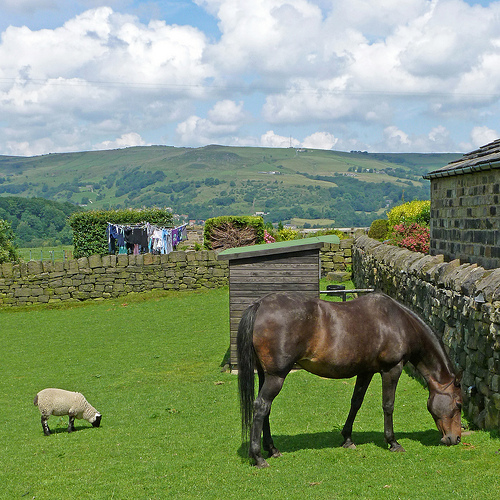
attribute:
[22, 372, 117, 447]
sheep — small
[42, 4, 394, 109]
clouds — big, white, fluffy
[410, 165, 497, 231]
house — big, brick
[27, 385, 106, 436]
small sheep — white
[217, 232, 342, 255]
roof — green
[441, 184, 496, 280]
wall — stoned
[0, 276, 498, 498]
grass — thick, luscious, green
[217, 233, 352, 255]
roof — green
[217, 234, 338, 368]
wooden shed — small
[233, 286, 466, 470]
horse — dark brown, grazing, brown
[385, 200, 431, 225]
flowers — yellow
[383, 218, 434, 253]
flowers — red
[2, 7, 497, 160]
sky — blue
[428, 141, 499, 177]
roof — gray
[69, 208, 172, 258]
tree — tall, green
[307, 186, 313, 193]
tree — tall, green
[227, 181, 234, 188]
tree — tall, green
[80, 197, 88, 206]
tree — tall, green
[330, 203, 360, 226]
tree — tall, green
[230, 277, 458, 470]
horse field — black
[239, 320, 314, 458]
leg — hind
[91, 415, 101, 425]
face — black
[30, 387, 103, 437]
sheep — small, grazing, wool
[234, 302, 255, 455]
tail — long, black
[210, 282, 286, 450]
tail — black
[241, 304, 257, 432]
tail — long, black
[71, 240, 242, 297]
wall — stoned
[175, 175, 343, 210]
shrubs — small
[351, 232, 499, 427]
wall — long, stoned, stone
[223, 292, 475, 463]
horse — black